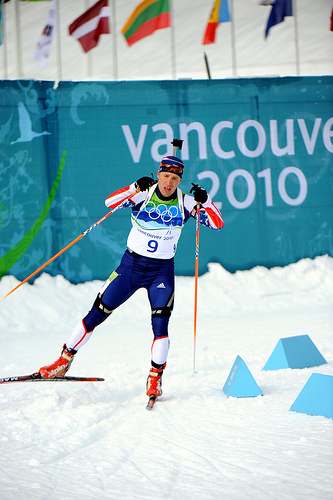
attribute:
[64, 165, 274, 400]
skier — skiing, coming, carrying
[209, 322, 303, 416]
marker — blue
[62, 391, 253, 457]
snow — white, bright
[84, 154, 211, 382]
man — wearing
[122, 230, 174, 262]
symbol — 9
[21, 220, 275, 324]
poles — orange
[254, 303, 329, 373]
triangle — blue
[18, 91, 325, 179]
gate — blue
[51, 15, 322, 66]
flags — flying, national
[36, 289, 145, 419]
leg — skier's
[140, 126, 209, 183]
cap — blue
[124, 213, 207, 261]
number — 9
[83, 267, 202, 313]
pants — blue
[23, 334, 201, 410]
shoes — red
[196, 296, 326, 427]
barriers — blue, small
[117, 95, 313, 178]
sign — white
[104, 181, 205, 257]
shirt — white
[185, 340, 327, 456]
ice — beautiful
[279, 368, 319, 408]
object — small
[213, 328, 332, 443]
objects — grouped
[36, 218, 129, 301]
sticks — held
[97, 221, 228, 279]
bib — 9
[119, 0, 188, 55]
flag — green